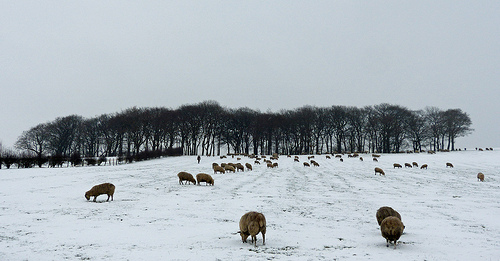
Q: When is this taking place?
A: Daytime.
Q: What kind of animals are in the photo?
A: Sheep.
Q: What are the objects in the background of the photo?
A: Trees.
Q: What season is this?
A: Winter.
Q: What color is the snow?
A: White.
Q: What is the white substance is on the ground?
A: Snow.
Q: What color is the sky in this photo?
A: White.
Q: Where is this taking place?
A: In the snowy field.